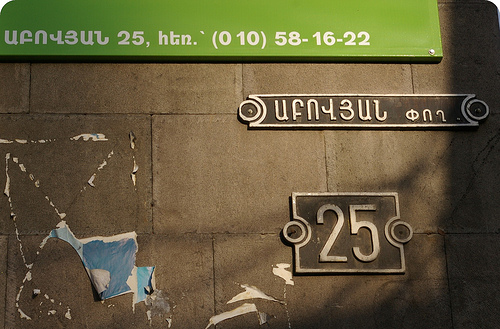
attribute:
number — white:
[313, 202, 351, 266]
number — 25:
[313, 201, 383, 266]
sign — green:
[2, 2, 447, 63]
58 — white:
[272, 25, 304, 49]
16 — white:
[310, 28, 338, 51]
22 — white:
[342, 26, 374, 52]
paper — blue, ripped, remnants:
[45, 215, 159, 313]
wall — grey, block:
[2, 3, 498, 326]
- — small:
[334, 33, 345, 46]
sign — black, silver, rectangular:
[280, 186, 412, 281]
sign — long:
[233, 90, 493, 135]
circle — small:
[237, 97, 263, 124]